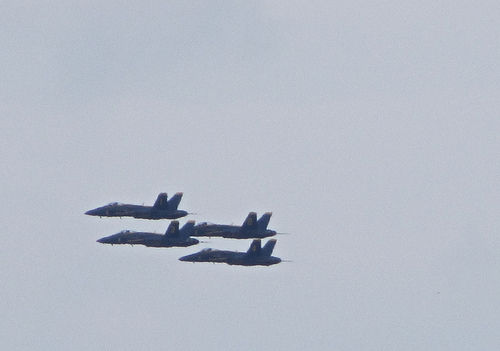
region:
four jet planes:
[82, 188, 293, 282]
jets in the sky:
[74, 182, 306, 284]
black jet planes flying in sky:
[63, 172, 313, 284]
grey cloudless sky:
[215, 104, 363, 171]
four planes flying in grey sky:
[54, 176, 343, 300]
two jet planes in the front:
[80, 187, 198, 279]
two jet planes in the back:
[187, 212, 297, 284]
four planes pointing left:
[76, 179, 303, 286]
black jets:
[90, 176, 282, 273]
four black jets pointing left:
[73, 182, 297, 286]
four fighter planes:
[62, 161, 369, 313]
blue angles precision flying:
[52, 164, 343, 311]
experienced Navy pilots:
[66, 161, 314, 326]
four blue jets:
[69, 158, 310, 295]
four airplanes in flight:
[66, 151, 329, 326]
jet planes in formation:
[68, 163, 328, 306]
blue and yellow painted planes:
[60, 155, 297, 307]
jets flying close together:
[64, 154, 325, 349]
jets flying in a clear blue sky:
[62, 108, 348, 317]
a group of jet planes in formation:
[55, 143, 325, 320]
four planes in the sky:
[84, 173, 285, 286]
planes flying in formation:
[71, 182, 290, 279]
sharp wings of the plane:
[148, 186, 188, 211]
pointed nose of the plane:
[79, 204, 94, 222]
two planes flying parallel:
[71, 177, 209, 259]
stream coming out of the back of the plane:
[277, 230, 289, 239]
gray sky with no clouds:
[3, 0, 499, 349]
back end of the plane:
[270, 254, 286, 265]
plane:
[73, 176, 198, 221]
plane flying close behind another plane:
[83, 209, 287, 246]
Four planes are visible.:
[81, 147, 253, 307]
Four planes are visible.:
[77, 197, 324, 348]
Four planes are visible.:
[142, 221, 256, 348]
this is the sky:
[252, 67, 498, 176]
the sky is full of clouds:
[298, 84, 435, 206]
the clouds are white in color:
[276, 85, 475, 193]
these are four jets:
[62, 187, 294, 280]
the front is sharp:
[82, 202, 105, 217]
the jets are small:
[83, 188, 288, 268]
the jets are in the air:
[80, 190, 297, 282]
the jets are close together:
[60, 164, 314, 287]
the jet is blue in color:
[203, 224, 220, 233]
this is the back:
[166, 219, 194, 235]